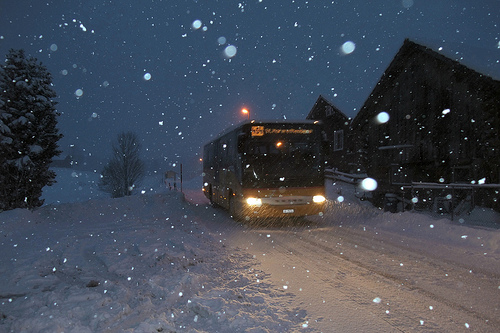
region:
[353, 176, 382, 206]
speck of snow in air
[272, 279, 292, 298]
speck of snow in air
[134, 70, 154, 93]
speck of snow in air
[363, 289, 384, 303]
speck of snow in air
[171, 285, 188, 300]
speck of snow in air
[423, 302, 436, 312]
speck of snow in air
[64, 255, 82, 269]
speck of snow in air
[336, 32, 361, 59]
speck of snow in air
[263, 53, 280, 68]
speck of snow in air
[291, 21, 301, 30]
speck of snow in air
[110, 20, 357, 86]
Snow falling at night.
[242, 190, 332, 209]
Headlights of a bus shining bright.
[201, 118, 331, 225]
Bus travelling in the snow.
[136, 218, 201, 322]
Footprints in the snow.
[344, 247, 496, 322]
Car, bus and truck tracks in the snow.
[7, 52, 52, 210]
Snow covered tree on the left.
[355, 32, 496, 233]
Dark building on the right.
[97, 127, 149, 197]
Leafless tree on the left.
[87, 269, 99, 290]
Dog poop in a bank of snow.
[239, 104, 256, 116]
Streetlight shining a bright white.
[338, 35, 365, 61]
small snowflake on the camera lens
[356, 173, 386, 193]
small snowflake on the camera lens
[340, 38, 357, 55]
small snowflake on the camera lens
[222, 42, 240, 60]
small snowflake on the camera lens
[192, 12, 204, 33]
small snowflake on the camera lens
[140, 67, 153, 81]
small snowflake on the camera lens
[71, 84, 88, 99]
small snowflake on the camera lens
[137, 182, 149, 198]
small snowflake on the camera lens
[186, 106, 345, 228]
bus in the snow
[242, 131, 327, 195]
windshield of a bus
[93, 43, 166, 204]
the snow is falling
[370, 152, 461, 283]
the snow is falling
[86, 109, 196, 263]
the snow is falling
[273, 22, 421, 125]
the snow is falling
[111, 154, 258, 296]
the snow is falling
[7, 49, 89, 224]
tree is covered with snow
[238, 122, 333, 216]
Front of a bus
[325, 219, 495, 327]
Road covered in snow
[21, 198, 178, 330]
Snow covered ground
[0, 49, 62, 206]
Pine tree on the roadside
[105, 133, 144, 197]
Leafless tree on roadside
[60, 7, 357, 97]
Snow falling from the sky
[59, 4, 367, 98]
Evening snow filled sky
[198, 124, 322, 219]
Bus on the road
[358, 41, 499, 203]
House by the roadside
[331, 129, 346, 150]
Window in a house